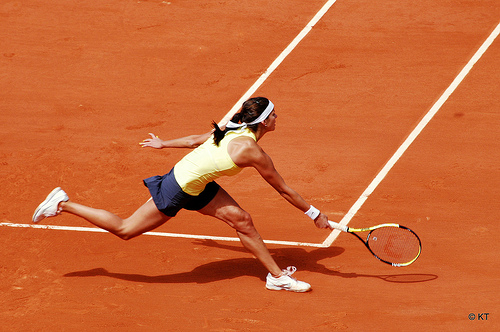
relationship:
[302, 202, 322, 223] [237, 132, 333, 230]
sweat band on arm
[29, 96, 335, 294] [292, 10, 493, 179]
player on court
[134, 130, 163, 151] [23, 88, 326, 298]
hand of player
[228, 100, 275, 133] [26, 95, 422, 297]
headband on player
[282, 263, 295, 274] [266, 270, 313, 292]
laces on shoe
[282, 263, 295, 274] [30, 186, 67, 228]
laces on shoe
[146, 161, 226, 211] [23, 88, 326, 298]
skirt on player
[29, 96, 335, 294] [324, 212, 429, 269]
player swinging racket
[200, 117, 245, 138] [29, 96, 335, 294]
tail on player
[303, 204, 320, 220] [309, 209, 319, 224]
sweat band on wrist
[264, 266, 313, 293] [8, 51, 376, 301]
shoe on player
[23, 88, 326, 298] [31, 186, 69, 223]
player has shoe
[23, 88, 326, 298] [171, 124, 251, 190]
player wearing shirt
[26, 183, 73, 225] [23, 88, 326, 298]
shoe of player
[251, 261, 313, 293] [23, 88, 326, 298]
shoe of player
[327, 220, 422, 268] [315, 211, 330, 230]
racket in hand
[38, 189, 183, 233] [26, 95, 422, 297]
right leg of player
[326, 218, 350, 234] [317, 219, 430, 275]
grip attached to racquet